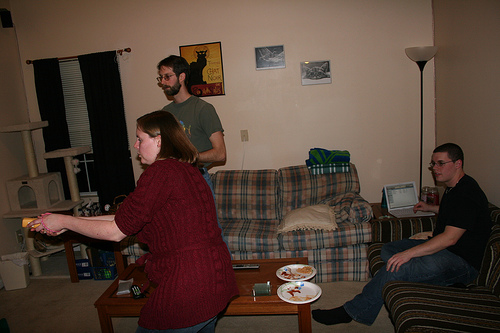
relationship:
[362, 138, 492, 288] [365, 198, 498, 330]
man sitting on couch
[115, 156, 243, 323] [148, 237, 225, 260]
sweater ties around waist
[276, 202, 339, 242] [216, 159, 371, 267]
pillow on couch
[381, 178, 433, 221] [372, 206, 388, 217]
laptop on table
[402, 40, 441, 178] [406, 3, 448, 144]
lamp in corner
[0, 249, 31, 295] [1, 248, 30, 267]
can has plastic bag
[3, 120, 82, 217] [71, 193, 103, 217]
cat house with toys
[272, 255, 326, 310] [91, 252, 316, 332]
plate of table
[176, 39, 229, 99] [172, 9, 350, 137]
picture hanging on wall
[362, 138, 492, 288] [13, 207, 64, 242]
man watching wii game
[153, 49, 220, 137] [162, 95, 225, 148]
man in green shirt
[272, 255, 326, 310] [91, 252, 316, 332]
plates on table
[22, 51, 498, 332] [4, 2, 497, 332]
people in a livingroom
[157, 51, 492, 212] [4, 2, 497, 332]
men in a room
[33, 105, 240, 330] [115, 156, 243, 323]
woman wearing red sweater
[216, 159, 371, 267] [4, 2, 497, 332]
sofa in room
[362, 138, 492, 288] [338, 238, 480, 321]
man with jeans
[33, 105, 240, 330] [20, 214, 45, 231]
woman holding controller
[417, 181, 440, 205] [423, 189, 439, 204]
candles in containers